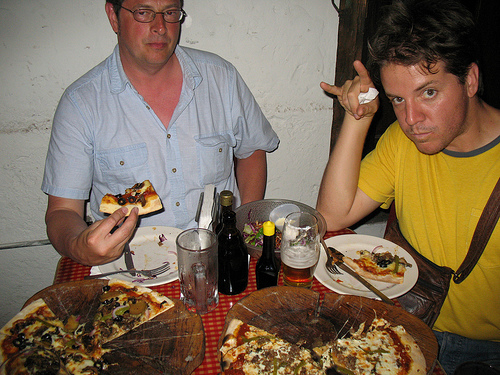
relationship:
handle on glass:
[193, 267, 207, 306] [278, 209, 323, 284]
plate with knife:
[313, 230, 419, 301] [337, 261, 391, 303]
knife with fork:
[337, 261, 391, 303] [318, 234, 341, 274]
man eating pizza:
[32, 0, 274, 296] [100, 180, 164, 220]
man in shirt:
[351, 70, 488, 327] [353, 153, 486, 309]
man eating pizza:
[351, 70, 488, 327] [286, 202, 427, 337]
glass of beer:
[278, 209, 323, 284] [284, 245, 320, 280]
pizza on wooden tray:
[0, 297, 97, 373] [0, 275, 206, 374]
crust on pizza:
[101, 195, 166, 215] [99, 181, 164, 217]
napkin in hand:
[357, 87, 381, 104] [319, 59, 381, 119]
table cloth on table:
[4, 242, 486, 372] [16, 235, 441, 374]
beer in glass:
[282, 246, 316, 285] [274, 203, 326, 291]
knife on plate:
[125, 244, 136, 281] [317, 233, 427, 313]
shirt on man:
[349, 114, 499, 339] [312, 0, 497, 375]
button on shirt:
[169, 167, 178, 174] [38, 36, 283, 256]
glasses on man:
[102, 0, 187, 25] [36, 1, 277, 265]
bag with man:
[342, 194, 477, 356] [306, 32, 499, 277]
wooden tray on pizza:
[2, 275, 204, 372] [224, 316, 425, 372]